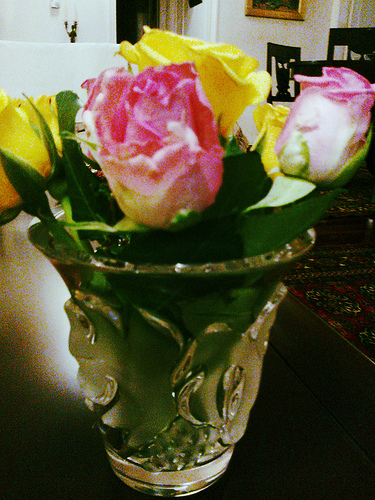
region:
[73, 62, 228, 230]
a pink flower in a vase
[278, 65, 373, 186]
a pink flower in a vase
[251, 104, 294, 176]
a yellow flower in a vase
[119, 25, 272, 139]
a yellow flower in a vase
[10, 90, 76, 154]
a yellow flower in a vase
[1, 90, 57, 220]
a yellow flower in a vase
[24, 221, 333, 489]
a clear glass vase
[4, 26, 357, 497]
a vase with yellow and pink flowers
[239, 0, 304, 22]
a picture on the wall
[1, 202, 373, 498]
a black table with a vase on it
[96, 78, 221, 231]
pink flower in vase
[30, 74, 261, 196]
yellow flowers in vase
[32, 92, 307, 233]
green leaves on flowers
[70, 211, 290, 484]
vase is dark green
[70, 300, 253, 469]
raised images on vase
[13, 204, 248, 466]
vase on black table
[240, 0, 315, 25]
brown picture frame on wall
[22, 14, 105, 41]
white wall behind table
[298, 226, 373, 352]
carpet is red and brown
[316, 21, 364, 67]
brown chair near wall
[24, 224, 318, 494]
a large flower pot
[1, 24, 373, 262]
these are yellow and pink flowers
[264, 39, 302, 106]
this is a black chair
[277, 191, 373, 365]
this is a colorful rug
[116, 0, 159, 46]
this is the doorway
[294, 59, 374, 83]
this is a black table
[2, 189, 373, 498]
this is a shiny floor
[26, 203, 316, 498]
the vase has design's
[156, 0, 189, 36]
these are colorful curtains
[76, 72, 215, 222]
Large pink rose with white portions near the bottom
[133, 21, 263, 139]
Top of a yellow rose beyond a pink rose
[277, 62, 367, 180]
White and pink rose with green leaves nearby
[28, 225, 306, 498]
Large gray face with a varying texture and lighter color patterns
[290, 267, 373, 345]
Rug on the ground with red patterns on the ground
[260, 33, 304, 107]
Black chair with patterns cut into the back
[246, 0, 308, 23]
Colorful painting with a light colored wooden frame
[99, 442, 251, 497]
White bottom of a porcelain vase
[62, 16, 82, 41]
Black candle stick holder in front of a white wall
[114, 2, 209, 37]
White doorway leading to a darkened room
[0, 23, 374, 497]
Flowers in a green vase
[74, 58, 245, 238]
A pink rose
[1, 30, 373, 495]
roses in a vase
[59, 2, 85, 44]
candles in a candle holder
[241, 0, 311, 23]
picture on a wall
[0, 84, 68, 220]
yellow color roses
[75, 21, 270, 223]
a pink and a yellow rose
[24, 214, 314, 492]
a green colored vase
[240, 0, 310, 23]
a gold framed picture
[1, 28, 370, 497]
a bunch of roses in a vase